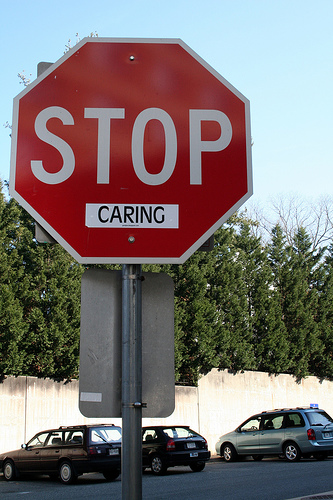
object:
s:
[29, 96, 76, 185]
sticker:
[89, 203, 174, 227]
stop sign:
[7, 29, 256, 266]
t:
[81, 105, 123, 186]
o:
[128, 101, 178, 187]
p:
[185, 103, 232, 197]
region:
[2, 9, 260, 307]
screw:
[126, 234, 134, 246]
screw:
[125, 51, 137, 67]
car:
[141, 410, 214, 477]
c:
[97, 203, 112, 226]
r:
[124, 205, 134, 229]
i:
[135, 205, 140, 226]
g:
[153, 201, 168, 225]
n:
[140, 203, 153, 226]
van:
[215, 401, 333, 462]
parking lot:
[0, 396, 333, 499]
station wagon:
[0, 421, 125, 494]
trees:
[251, 192, 291, 376]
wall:
[7, 358, 331, 452]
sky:
[4, 7, 324, 213]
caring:
[97, 207, 172, 221]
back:
[78, 274, 175, 419]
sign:
[79, 266, 180, 421]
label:
[75, 388, 110, 410]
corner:
[28, 225, 51, 250]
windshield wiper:
[95, 426, 113, 445]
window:
[87, 430, 126, 444]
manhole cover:
[301, 489, 333, 497]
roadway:
[249, 452, 327, 496]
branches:
[318, 227, 328, 240]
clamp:
[114, 271, 153, 283]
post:
[121, 262, 144, 498]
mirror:
[162, 432, 174, 437]